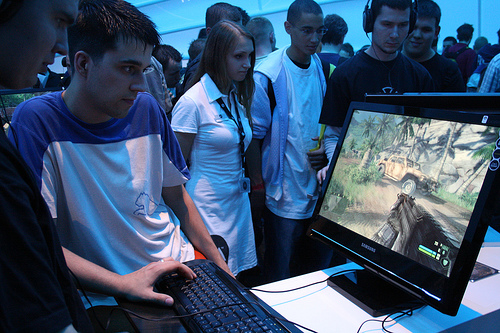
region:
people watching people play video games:
[0, 0, 498, 331]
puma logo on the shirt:
[125, 185, 175, 236]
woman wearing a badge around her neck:
[162, 15, 275, 295]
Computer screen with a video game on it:
[298, 97, 498, 317]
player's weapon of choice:
[365, 188, 462, 283]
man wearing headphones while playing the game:
[310, 0, 447, 190]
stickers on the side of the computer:
[482, 130, 498, 180]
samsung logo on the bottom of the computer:
[355, 238, 383, 258]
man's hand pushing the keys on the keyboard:
[116, 245, 213, 314]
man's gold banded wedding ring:
[155, 255, 170, 266]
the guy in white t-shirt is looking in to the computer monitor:
[26, 1, 497, 311]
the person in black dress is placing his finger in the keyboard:
[2, 1, 497, 326]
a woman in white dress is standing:
[170, 17, 255, 277]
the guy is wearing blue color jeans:
[250, 0, 325, 270]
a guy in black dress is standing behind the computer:
[315, 0, 430, 265]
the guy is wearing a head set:
[320, 0, 436, 235]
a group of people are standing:
[180, 2, 496, 269]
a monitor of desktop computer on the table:
[305, 85, 495, 325]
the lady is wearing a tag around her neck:
[167, 20, 254, 272]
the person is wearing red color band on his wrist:
[247, 0, 331, 272]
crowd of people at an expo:
[13, 0, 490, 315]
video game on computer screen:
[320, 107, 491, 247]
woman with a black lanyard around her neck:
[200, 75, 254, 196]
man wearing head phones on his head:
[354, 0, 430, 65]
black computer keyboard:
[165, 233, 308, 325]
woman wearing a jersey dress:
[180, 0, 276, 279]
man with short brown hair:
[75, 3, 167, 132]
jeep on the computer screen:
[365, 150, 445, 195]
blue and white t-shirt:
[10, 83, 191, 289]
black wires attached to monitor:
[236, 252, 428, 331]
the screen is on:
[309, 86, 490, 313]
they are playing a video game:
[1, 1, 499, 331]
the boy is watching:
[93, 42, 148, 107]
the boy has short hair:
[66, 0, 164, 69]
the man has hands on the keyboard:
[130, 259, 195, 309]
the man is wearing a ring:
[158, 260, 165, 262]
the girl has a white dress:
[173, 78, 259, 271]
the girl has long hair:
[207, 20, 252, 128]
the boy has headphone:
[357, 0, 412, 49]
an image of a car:
[376, 157, 442, 200]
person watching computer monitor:
[52, 26, 177, 328]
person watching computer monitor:
[179, 26, 255, 271]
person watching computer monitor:
[282, 4, 324, 249]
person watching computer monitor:
[357, 6, 407, 120]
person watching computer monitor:
[418, 9, 437, 70]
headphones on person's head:
[356, 4, 380, 45]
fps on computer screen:
[338, 137, 438, 244]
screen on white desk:
[219, 243, 408, 327]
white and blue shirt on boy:
[34, 84, 212, 291]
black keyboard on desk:
[147, 254, 252, 331]